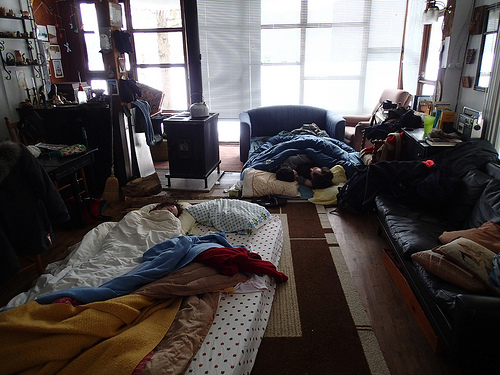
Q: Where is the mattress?
A: The mattress is on the floor.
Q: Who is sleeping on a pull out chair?
A: Two people are sleeping in a pull out chair.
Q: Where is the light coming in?
A: The light is coming in from the windows.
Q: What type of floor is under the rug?
A: Wood.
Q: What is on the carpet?
A: A mattress.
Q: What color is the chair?
A: Blue.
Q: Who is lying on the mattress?
A: A person.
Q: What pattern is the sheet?
A: Polka dot.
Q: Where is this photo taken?
A: In a small room.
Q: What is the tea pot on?
A: A wood stove.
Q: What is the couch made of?
A: Leather.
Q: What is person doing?
A: Sleeping.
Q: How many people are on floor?
A: Three.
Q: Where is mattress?
A: On floor.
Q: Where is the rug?
A: In apartment.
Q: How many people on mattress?
A: Two.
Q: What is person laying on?
A: Mattress.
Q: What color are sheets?
A: White.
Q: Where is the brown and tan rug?
A: On the floor.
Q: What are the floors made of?
A: Wood.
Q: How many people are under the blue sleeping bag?
A: Two.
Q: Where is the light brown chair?
A: Near windows.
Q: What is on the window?
A: Blinds.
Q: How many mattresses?
A: 1.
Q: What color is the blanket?
A: Yellow.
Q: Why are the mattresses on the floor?
A: To sleep.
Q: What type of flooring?
A: Wood.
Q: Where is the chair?
A: In front of the window.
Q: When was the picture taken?
A: Daytime.